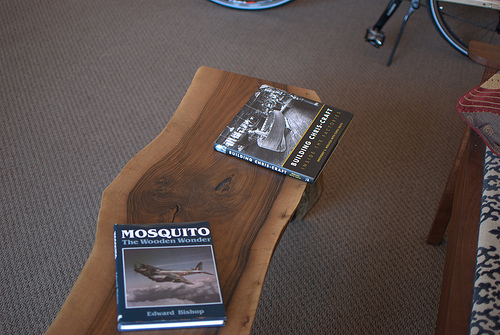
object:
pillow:
[455, 67, 500, 155]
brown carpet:
[0, 0, 500, 335]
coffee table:
[44, 64, 324, 335]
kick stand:
[382, 0, 425, 68]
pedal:
[364, 0, 399, 49]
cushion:
[468, 145, 500, 335]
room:
[0, 0, 500, 335]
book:
[212, 81, 354, 186]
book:
[113, 220, 228, 332]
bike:
[196, 0, 499, 67]